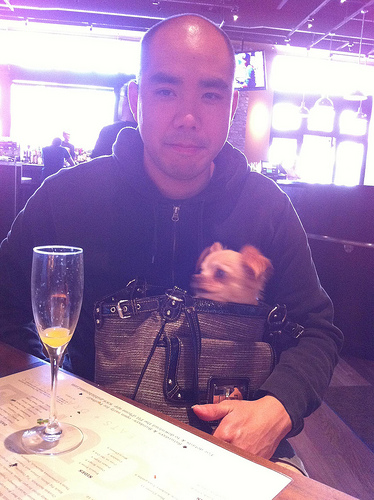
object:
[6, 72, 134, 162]
window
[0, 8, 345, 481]
man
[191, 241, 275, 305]
dog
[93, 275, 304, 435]
purse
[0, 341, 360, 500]
table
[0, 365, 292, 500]
menu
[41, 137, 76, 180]
man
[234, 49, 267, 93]
television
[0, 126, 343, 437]
jacket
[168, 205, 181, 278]
zipper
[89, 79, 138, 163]
people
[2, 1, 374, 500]
restaurant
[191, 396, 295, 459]
mans left hand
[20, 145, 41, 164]
bottles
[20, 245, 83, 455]
champaigne flute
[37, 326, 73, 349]
orange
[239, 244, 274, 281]
ears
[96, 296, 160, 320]
latch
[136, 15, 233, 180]
mans face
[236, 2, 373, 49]
ceiling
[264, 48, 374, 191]
light glare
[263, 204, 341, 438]
his arm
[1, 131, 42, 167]
bar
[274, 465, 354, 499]
table top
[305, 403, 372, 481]
floor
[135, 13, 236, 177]
his head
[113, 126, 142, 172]
hood